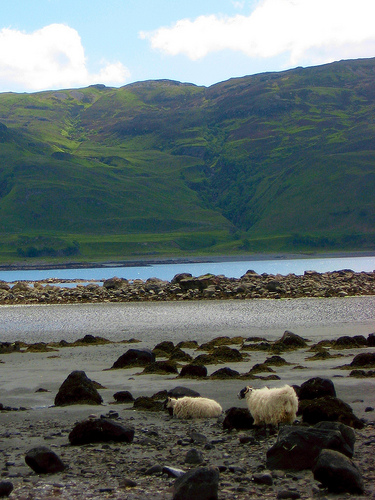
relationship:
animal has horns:
[240, 379, 306, 424] [238, 382, 246, 404]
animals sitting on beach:
[145, 370, 302, 438] [7, 309, 367, 489]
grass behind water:
[47, 225, 303, 261] [190, 254, 349, 277]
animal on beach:
[237, 381, 298, 429] [7, 309, 367, 489]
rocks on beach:
[49, 366, 358, 485] [7, 309, 367, 489]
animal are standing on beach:
[237, 381, 298, 429] [7, 309, 367, 489]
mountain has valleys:
[21, 89, 349, 225] [128, 93, 239, 213]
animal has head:
[237, 381, 298, 429] [235, 382, 260, 408]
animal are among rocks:
[237, 381, 298, 429] [49, 366, 358, 485]